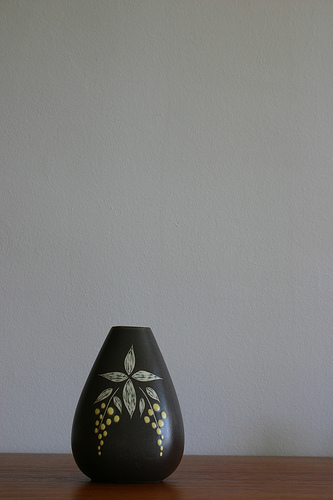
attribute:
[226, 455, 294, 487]
table — wooden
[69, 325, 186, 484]
vase — dark brown, chocolate ,  painted docorations  , black, oval, teardrop shaped, painted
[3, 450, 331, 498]
surface — medium brown, flat, wooden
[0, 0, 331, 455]
wall — dull,  plain, gray, white, rough, empty 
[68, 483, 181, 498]
shadow — dark brown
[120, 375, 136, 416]
leaf — large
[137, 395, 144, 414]
leaf — small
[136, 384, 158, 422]
stem — long, thin, gray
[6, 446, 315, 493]
table — brown  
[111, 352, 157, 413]
flowers — patterns 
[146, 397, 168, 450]
colour — yellow 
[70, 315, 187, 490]
vase — single , empty, teardrop shaped black, decorative deisgn 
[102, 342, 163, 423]
flowers — hand painted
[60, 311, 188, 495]
vase — under  , black surface 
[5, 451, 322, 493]
furniture — wood 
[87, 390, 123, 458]
grapes — white, left side 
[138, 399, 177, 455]
grapes — right side, white 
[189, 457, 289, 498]
wood — cherry finish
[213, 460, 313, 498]
table — brown wooden 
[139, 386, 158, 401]
petal —  green 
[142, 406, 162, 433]
dots — round,yellow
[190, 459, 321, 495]
surface — wooden table 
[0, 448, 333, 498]
table — brown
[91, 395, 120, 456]
dots — yellow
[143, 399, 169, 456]
dots — yellow